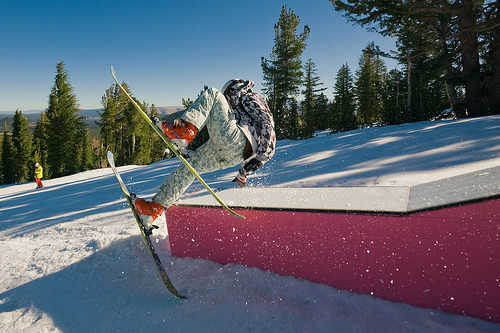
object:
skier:
[33, 162, 44, 189]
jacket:
[34, 166, 44, 178]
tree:
[260, 4, 306, 140]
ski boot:
[151, 115, 200, 151]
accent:
[188, 128, 195, 136]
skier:
[117, 71, 283, 234]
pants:
[35, 178, 44, 188]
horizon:
[9, 116, 496, 141]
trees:
[79, 124, 93, 172]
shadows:
[0, 187, 126, 239]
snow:
[0, 115, 500, 332]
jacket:
[220, 78, 281, 177]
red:
[39, 184, 40, 185]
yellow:
[40, 173, 41, 174]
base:
[158, 203, 500, 326]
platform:
[162, 159, 500, 330]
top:
[172, 163, 500, 211]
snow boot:
[131, 195, 166, 230]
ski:
[104, 64, 248, 224]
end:
[106, 65, 120, 79]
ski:
[104, 147, 192, 300]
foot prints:
[299, 175, 386, 188]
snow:
[248, 172, 269, 191]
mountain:
[0, 116, 498, 332]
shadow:
[383, 123, 493, 173]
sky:
[2, 0, 405, 105]